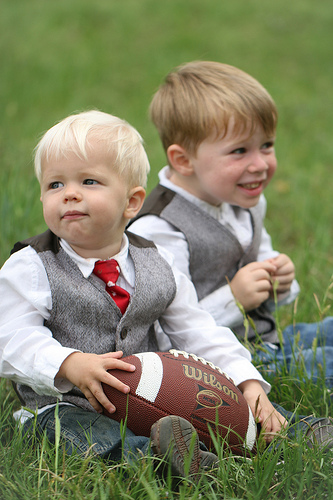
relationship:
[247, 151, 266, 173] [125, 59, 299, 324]
nose on boy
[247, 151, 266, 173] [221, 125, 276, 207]
nose on face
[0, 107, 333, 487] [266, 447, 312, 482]
boy on grass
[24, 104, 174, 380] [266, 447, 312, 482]
boy on grass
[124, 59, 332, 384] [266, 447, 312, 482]
boy on grass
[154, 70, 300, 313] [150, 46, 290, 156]
boy with red hair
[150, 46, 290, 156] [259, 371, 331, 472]
red hair on grass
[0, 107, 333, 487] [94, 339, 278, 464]
boy holding football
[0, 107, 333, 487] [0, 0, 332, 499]
boy in grass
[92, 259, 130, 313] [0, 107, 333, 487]
red tie on boy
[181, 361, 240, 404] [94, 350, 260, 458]
wilson written on a football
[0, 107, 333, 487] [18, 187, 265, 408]
boy wearing vests